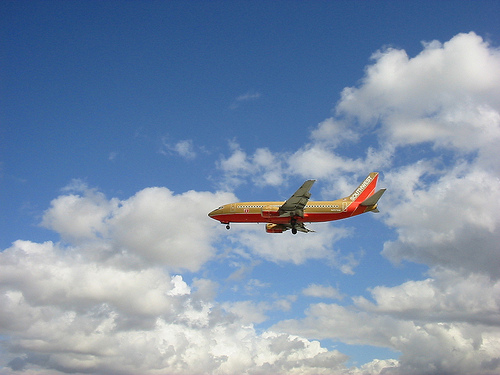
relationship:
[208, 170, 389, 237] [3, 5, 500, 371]
plane in sky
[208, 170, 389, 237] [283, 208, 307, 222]
plane has landing gear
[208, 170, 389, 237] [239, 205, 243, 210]
plane has window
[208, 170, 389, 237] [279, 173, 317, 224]
plane has wing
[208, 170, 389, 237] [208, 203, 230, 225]
plane has nose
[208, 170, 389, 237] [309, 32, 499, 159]
plane in front of cloud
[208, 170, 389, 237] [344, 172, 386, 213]
plane has tail fin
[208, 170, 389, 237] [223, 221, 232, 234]
plane has front wheel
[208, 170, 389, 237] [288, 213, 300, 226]
plane has wheel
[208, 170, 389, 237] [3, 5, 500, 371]
plane flying in sky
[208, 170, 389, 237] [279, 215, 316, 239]
plane has wing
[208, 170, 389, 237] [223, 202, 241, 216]
plane has cockpit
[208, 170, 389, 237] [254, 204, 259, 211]
plane has window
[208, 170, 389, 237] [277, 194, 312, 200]
plane has propeller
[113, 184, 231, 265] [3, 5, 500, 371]
cloud in sky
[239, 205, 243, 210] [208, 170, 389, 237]
window on plane